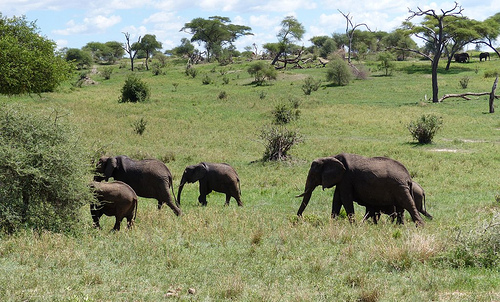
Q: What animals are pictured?
A: Elephants.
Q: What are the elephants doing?
A: Walking.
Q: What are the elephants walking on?
A: The grass.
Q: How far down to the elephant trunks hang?
A: To the ground.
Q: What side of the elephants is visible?
A: The left side.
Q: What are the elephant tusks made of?
A: Ivory.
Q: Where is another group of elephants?
A: Top right of the image.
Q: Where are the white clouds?
A: All throughout the sky.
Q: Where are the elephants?
A: They are outside.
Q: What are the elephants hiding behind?
A: A bush.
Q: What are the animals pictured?
A: Elephants.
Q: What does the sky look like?
A: Bright blue.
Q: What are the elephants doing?
A: They are walking.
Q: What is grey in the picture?
A: The elephants.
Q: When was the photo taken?
A: Daytime.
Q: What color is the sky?
A: Blue.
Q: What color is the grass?
A: Green.